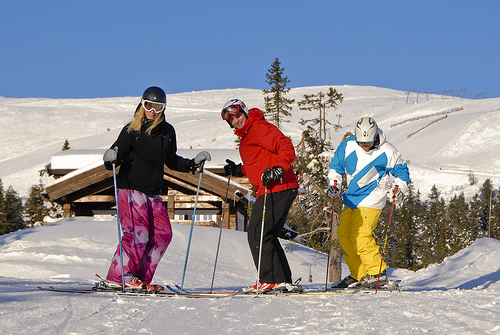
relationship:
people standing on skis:
[101, 86, 209, 289] [94, 140, 209, 300]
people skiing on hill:
[101, 86, 209, 289] [0, 216, 496, 330]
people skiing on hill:
[219, 97, 294, 289] [0, 216, 496, 330]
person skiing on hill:
[320, 109, 415, 296] [0, 216, 496, 330]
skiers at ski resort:
[58, 70, 453, 314] [40, 120, 236, 288]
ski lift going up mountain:
[331, 80, 498, 134] [8, 59, 494, 256]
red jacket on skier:
[185, 83, 295, 187] [221, 96, 297, 282]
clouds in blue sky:
[341, 42, 371, 64] [1, 0, 498, 98]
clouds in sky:
[323, 31, 376, 61] [3, 2, 498, 95]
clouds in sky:
[147, 27, 328, 65] [3, 2, 498, 95]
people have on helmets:
[87, 53, 427, 317] [115, 73, 390, 150]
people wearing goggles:
[88, 58, 399, 317] [216, 90, 246, 127]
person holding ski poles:
[320, 109, 415, 296] [321, 176, 398, 298]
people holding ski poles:
[101, 86, 209, 289] [108, 147, 208, 277]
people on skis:
[219, 97, 294, 289] [165, 275, 340, 302]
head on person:
[349, 112, 387, 158] [320, 109, 415, 296]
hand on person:
[387, 184, 408, 212] [305, 101, 415, 300]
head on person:
[214, 95, 249, 131] [216, 96, 302, 291]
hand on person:
[219, 157, 244, 187] [213, 93, 283, 193]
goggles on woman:
[141, 98, 165, 111] [75, 77, 205, 309]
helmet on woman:
[143, 81, 167, 106] [97, 80, 214, 286]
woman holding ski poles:
[104, 79, 202, 301] [90, 157, 157, 304]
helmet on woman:
[220, 97, 248, 119] [216, 97, 299, 293]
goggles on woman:
[217, 99, 245, 122] [224, 93, 318, 309]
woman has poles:
[211, 94, 304, 296] [214, 166, 268, 297]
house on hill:
[42, 135, 270, 237] [2, 87, 498, 189]